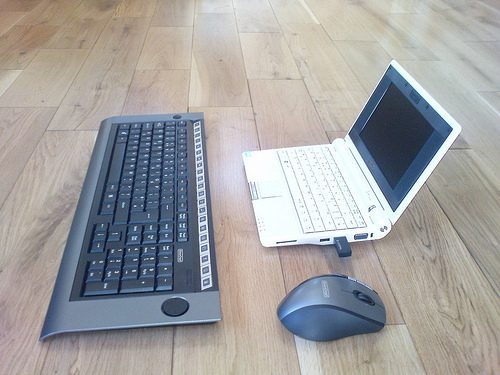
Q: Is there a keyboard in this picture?
A: Yes, there is a keyboard.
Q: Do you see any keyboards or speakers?
A: Yes, there is a keyboard.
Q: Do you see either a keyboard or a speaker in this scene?
A: Yes, there is a keyboard.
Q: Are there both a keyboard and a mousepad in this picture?
A: No, there is a keyboard but no mouse pads.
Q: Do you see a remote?
A: No, there are no remote controls.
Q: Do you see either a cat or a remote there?
A: No, there are no remote controls or cats.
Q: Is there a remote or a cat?
A: No, there are no remote controls or cats.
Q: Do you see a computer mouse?
A: Yes, there is a computer mouse.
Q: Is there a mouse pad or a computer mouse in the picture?
A: Yes, there is a computer mouse.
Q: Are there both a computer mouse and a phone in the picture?
A: No, there is a computer mouse but no phones.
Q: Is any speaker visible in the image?
A: No, there are no speakers.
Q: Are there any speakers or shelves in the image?
A: No, there are no speakers or shelves.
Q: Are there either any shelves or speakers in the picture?
A: No, there are no speakers or shelves.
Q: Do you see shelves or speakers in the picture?
A: No, there are no speakers or shelves.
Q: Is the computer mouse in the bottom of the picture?
A: Yes, the computer mouse is in the bottom of the image.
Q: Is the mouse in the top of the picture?
A: No, the mouse is in the bottom of the image.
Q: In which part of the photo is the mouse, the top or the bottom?
A: The mouse is in the bottom of the image.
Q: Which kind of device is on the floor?
A: The device is a computer mouse.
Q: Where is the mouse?
A: The mouse is on the floor.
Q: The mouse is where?
A: The mouse is on the floor.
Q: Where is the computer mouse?
A: The mouse is on the floor.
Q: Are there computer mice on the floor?
A: Yes, there is a computer mouse on the floor.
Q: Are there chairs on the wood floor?
A: No, there is a computer mouse on the floor.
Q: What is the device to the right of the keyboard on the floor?
A: The device is a computer mouse.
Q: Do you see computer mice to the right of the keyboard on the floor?
A: Yes, there is a computer mouse to the right of the keyboard.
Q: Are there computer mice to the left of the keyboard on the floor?
A: No, the computer mouse is to the right of the keyboard.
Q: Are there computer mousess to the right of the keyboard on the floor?
A: No, there is a computer mouse to the right of the keyboard.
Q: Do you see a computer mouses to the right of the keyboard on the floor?
A: No, there is a computer mouse to the right of the keyboard.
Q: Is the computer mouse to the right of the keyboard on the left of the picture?
A: Yes, the computer mouse is to the right of the keyboard.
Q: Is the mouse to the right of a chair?
A: No, the mouse is to the right of the keyboard.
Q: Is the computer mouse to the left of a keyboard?
A: No, the computer mouse is to the right of a keyboard.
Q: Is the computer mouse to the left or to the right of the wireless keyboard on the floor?
A: The computer mouse is to the right of the keyboard.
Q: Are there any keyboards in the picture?
A: Yes, there is a keyboard.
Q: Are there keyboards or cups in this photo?
A: Yes, there is a keyboard.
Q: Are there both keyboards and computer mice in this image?
A: Yes, there are both a keyboard and a computer mouse.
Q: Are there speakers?
A: No, there are no speakers.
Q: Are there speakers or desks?
A: No, there are no speakers or desks.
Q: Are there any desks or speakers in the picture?
A: No, there are no speakers or desks.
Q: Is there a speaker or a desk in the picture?
A: No, there are no speakers or desks.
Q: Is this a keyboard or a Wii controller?
A: This is a keyboard.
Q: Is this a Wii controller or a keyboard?
A: This is a keyboard.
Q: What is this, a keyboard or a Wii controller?
A: This is a keyboard.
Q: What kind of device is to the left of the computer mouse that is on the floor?
A: The device is a keyboard.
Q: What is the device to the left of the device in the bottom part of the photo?
A: The device is a keyboard.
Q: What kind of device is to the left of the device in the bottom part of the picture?
A: The device is a keyboard.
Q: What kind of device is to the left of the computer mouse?
A: The device is a keyboard.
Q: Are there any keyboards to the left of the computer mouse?
A: Yes, there is a keyboard to the left of the computer mouse.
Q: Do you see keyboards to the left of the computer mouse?
A: Yes, there is a keyboard to the left of the computer mouse.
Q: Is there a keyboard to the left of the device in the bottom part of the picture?
A: Yes, there is a keyboard to the left of the computer mouse.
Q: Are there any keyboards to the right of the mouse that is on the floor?
A: No, the keyboard is to the left of the mouse.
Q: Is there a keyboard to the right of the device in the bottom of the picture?
A: No, the keyboard is to the left of the mouse.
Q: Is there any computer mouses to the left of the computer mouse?
A: No, there is a keyboard to the left of the computer mouse.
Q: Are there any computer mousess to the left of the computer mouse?
A: No, there is a keyboard to the left of the computer mouse.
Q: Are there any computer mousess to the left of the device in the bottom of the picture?
A: No, there is a keyboard to the left of the computer mouse.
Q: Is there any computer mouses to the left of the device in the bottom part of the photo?
A: No, there is a keyboard to the left of the computer mouse.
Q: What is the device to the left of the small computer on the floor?
A: The device is a keyboard.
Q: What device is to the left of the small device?
A: The device is a keyboard.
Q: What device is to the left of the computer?
A: The device is a keyboard.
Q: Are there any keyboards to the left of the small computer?
A: Yes, there is a keyboard to the left of the computer.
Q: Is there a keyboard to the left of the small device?
A: Yes, there is a keyboard to the left of the computer.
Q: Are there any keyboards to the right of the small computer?
A: No, the keyboard is to the left of the computer.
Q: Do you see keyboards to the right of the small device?
A: No, the keyboard is to the left of the computer.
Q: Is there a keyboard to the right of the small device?
A: No, the keyboard is to the left of the computer.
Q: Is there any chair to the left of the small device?
A: No, there is a keyboard to the left of the computer.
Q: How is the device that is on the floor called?
A: The device is a keyboard.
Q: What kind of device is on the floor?
A: The device is a keyboard.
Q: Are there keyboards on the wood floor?
A: Yes, there is a keyboard on the floor.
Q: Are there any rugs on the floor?
A: No, there is a keyboard on the floor.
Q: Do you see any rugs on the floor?
A: No, there is a keyboard on the floor.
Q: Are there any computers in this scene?
A: Yes, there is a computer.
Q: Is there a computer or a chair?
A: Yes, there is a computer.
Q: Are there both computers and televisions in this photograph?
A: No, there is a computer but no televisions.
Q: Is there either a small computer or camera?
A: Yes, there is a small computer.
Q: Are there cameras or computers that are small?
A: Yes, the computer is small.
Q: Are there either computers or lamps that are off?
A: Yes, the computer is off.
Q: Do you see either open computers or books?
A: Yes, there is an open computer.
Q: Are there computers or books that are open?
A: Yes, the computer is open.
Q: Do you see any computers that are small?
A: Yes, there is a small computer.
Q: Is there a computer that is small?
A: Yes, there is a computer that is small.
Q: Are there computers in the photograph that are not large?
A: Yes, there is a small computer.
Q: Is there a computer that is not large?
A: Yes, there is a small computer.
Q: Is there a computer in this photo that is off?
A: Yes, there is a computer that is off.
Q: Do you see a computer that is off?
A: Yes, there is a computer that is off.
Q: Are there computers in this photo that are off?
A: Yes, there is a computer that is off.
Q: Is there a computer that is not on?
A: Yes, there is a computer that is off.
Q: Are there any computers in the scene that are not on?
A: Yes, there is a computer that is off.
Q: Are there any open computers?
A: Yes, there is an open computer.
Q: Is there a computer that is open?
A: Yes, there is a computer that is open.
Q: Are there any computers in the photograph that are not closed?
A: Yes, there is a open computer.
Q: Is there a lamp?
A: No, there are no lamps.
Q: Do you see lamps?
A: No, there are no lamps.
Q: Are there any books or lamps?
A: No, there are no lamps or books.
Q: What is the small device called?
A: The device is a computer.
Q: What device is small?
A: The device is a computer.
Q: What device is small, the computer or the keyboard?
A: The computer is small.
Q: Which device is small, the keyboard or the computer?
A: The computer is small.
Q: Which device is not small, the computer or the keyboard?
A: The keyboard is not small.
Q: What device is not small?
A: The device is a keyboard.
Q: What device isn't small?
A: The device is a keyboard.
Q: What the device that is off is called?
A: The device is a computer.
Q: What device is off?
A: The device is a computer.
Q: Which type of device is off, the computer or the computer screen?
A: The computer is off.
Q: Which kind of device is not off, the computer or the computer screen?
A: The screen is not off.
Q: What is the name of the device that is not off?
A: The device is a screen.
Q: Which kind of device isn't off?
A: The device is a screen.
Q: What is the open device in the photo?
A: The device is a computer.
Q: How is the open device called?
A: The device is a computer.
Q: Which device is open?
A: The device is a computer.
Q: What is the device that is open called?
A: The device is a computer.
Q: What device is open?
A: The device is a computer.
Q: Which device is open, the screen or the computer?
A: The computer is open.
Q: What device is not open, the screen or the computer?
A: The screen is not open.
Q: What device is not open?
A: The device is a screen.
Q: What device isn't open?
A: The device is a screen.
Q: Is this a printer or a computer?
A: This is a computer.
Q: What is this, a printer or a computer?
A: This is a computer.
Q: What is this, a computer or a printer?
A: This is a computer.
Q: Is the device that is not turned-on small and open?
A: Yes, the computer is small and open.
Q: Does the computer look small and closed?
A: No, the computer is small but open.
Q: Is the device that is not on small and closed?
A: No, the computer is small but open.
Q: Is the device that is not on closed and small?
A: No, the computer is small but open.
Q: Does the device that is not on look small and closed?
A: No, the computer is small but open.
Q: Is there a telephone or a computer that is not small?
A: No, there is a computer but it is small.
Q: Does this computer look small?
A: Yes, the computer is small.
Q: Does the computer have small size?
A: Yes, the computer is small.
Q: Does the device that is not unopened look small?
A: Yes, the computer is small.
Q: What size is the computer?
A: The computer is small.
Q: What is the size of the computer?
A: The computer is small.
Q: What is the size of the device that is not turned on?
A: The computer is small.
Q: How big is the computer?
A: The computer is small.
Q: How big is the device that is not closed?
A: The computer is small.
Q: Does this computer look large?
A: No, the computer is small.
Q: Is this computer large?
A: No, the computer is small.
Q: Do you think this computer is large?
A: No, the computer is small.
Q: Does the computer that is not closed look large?
A: No, the computer is small.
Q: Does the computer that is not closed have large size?
A: No, the computer is small.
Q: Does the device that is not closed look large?
A: No, the computer is small.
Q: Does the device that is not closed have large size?
A: No, the computer is small.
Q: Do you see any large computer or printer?
A: No, there is a computer but it is small.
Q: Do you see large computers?
A: No, there is a computer but it is small.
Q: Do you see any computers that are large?
A: No, there is a computer but it is small.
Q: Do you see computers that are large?
A: No, there is a computer but it is small.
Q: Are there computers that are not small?
A: No, there is a computer but it is small.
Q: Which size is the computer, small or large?
A: The computer is small.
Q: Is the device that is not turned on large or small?
A: The computer is small.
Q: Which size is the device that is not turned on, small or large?
A: The computer is small.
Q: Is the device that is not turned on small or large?
A: The computer is small.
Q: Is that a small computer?
A: Yes, that is a small computer.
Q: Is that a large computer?
A: No, that is a small computer.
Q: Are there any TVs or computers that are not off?
A: No, there is a computer but it is off.